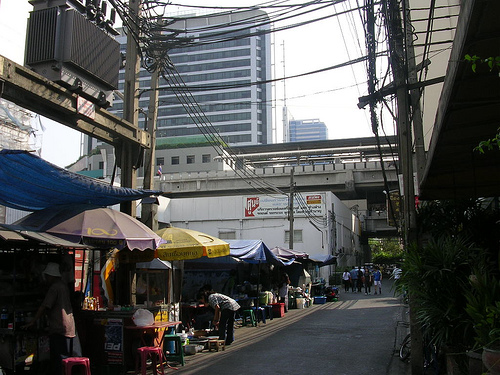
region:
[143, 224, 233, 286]
yellow umbrella on pole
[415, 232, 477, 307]
green leaves on vegetation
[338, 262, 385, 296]
people walking on street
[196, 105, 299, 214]
lines suspended in the air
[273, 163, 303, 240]
pole with lines on each side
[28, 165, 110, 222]
blue tarp over umbrella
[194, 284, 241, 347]
person bending over away from road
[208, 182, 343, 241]
white building with flat roof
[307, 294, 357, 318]
shadow of lines on street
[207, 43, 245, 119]
windows on side of building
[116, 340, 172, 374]
a red stool on the street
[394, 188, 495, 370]
potted plants along the street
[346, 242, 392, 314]
people walking in the street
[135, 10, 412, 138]
wires above the street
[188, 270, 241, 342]
a woman is bent over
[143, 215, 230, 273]
the umbrella is yellow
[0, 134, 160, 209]
a blue tarp is hanging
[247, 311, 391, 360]
the road is dark grey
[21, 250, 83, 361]
man wearing a white hat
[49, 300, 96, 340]
the sun on the man`s back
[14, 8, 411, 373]
Scenery of little shops selling goods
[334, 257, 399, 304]
People walking down street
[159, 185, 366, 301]
White building on street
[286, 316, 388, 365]
Grey street where vendors sell goods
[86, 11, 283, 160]
Grey and white building behind shops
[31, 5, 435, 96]
Black telephone lines covering street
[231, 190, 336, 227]
Red and white sign on white building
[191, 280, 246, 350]
Lady with light top and blue pants looking at items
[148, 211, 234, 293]
One yellow umbrella vendor stand selling items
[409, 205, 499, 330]
Dark green bush located on side of street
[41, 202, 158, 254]
purple umbrella with gold symbol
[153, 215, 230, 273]
yellow umbrella with writing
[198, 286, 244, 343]
woman wearing long pants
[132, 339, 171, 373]
red small stool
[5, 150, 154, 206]
blur tarp connected to building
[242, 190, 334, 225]
white sign on the side of building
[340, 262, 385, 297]
group of people walking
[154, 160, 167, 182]
flag on top of building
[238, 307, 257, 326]
small green stool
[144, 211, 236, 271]
A large yellow umbrella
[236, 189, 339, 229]
A sign on the side of the building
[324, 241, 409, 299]
A group of pedestrians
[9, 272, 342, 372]
Restaurants and a street market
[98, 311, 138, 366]
Part of a pepsi sign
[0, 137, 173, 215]
A large blue tarp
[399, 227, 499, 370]
A bunch of plants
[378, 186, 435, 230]
Signs for different businesses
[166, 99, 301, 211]
Telephone wires above the street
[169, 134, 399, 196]
A bridge over the alley